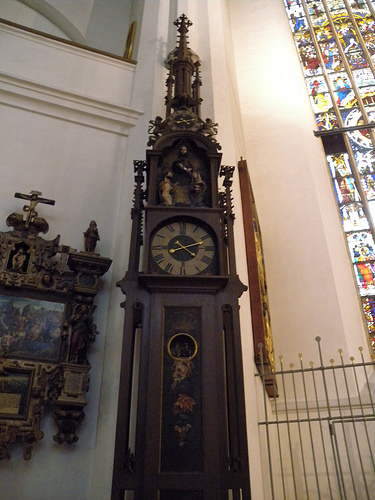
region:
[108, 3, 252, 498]
Floor clock with ornaments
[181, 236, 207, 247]
Hour hand of floor clock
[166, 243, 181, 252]
Minute hand floor clock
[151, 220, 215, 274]
Hour mark with roman numbers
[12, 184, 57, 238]
Cross with Jesus on.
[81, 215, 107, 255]
Statue of Virgin Mary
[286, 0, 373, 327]
Stained glass window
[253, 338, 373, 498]
Metal grille in a church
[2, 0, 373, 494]
Floor clock in a church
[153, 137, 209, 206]
Ornament in a floor clock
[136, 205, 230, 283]
The time on this clock is 4:10 pm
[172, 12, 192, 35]
There is a symbol of a cross at the top of this clock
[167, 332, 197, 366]
There is a circle at the bottom of the clock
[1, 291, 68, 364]
There is a picture hanging on the wall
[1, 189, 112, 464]
The frame is made from wood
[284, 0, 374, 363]
The window has a bars on it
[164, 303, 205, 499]
There is a rectangle designed underneath the clock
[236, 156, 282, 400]
There is a picture on the left side of the clock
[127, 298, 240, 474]
There is an rectangular slot on each side of the clock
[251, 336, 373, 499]
There is a metal bar designed with balls on top of each bar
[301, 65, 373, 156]
Stained glass windows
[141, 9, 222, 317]
Very tall clock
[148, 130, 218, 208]
Religious figurines above a clock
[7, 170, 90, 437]
Religious painting and frame on wall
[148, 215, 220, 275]
Hands of a clock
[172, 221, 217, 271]
Roman numerals on a clock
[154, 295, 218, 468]
Religious drawings on front of a clock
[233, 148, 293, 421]
Framed picture on wall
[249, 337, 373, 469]
Ornate decoration against a wall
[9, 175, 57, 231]
Cross on top of a painting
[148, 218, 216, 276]
clock face with roman numerals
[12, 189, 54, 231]
crucifix with Jesus Christ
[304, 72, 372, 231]
colorful stained glass window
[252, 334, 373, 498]
iron railings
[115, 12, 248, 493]
decorative dark wooden clock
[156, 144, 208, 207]
religious statues in shelf of clock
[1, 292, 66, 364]
religious portrait hanging on wall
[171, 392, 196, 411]
painted leaves on clock front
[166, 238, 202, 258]
gold clock hands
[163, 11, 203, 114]
steeple on top of clock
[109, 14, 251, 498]
Ornate grandfather clock.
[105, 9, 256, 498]
Grandfather clock embellished with religious images.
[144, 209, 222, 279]
Face of the clock.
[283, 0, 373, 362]
Stained glass window panels.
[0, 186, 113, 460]
Religious artwork hanging on the wall.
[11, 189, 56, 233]
Crucifix showing Jesus on the cross.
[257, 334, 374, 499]
Metal gate.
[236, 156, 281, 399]
Artwork hanging from the wall.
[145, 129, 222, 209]
Religious images on the clock.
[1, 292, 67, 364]
Painting.